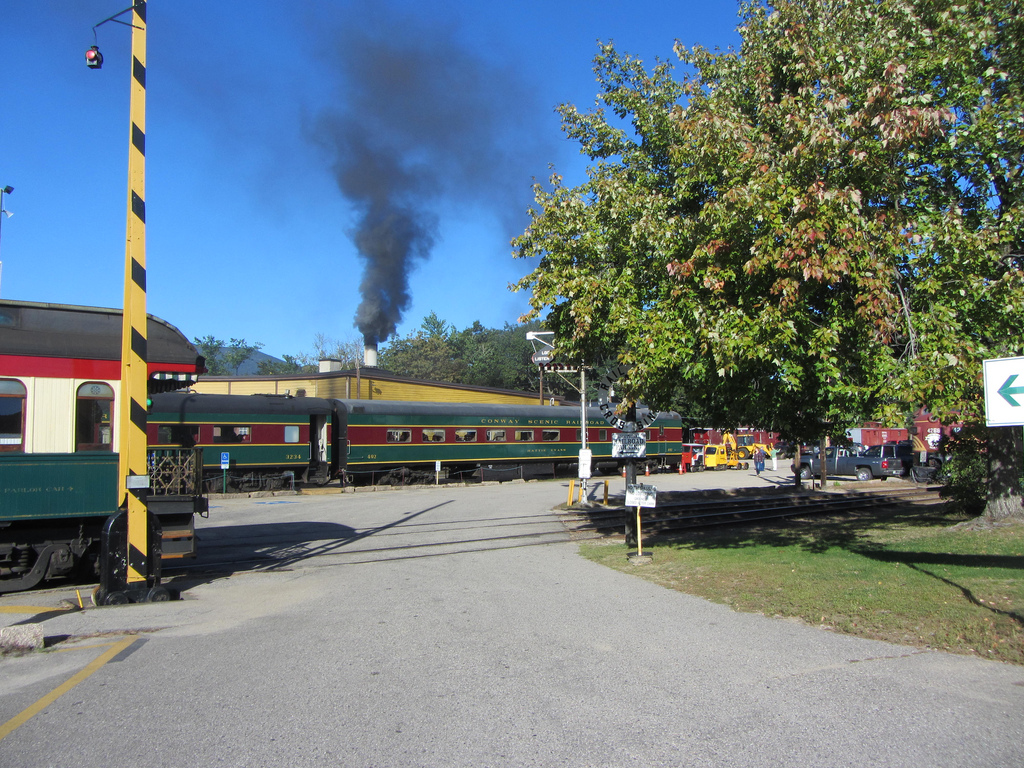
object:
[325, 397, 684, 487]
train car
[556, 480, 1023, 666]
grass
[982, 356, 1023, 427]
sign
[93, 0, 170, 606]
beam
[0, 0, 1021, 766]
air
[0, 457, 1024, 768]
road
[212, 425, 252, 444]
window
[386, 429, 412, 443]
window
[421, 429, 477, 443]
window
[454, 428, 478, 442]
window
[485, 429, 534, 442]
window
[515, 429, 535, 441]
window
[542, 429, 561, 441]
window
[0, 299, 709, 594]
train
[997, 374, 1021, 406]
arrow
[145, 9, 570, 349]
smoke